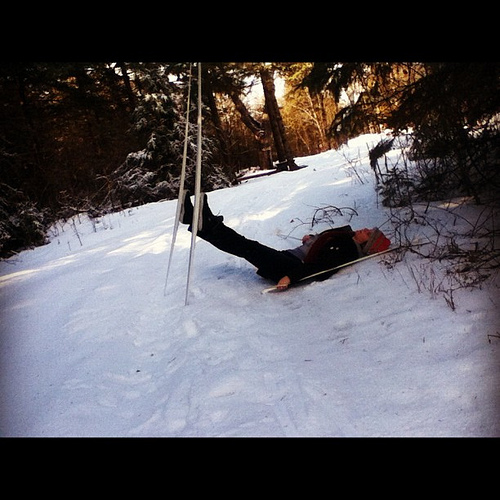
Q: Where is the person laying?
A: Ground.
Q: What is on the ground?
A: Snow.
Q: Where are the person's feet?
A: In skis.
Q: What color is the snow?
A: White.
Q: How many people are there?
A: One.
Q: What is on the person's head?
A: Hat.